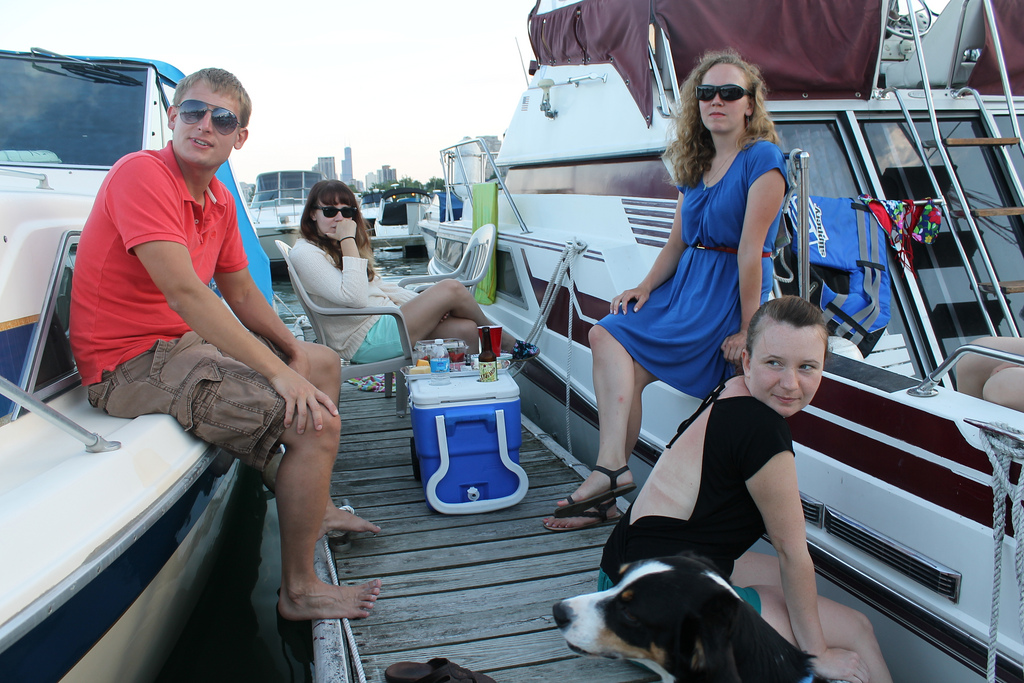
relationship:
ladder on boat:
[903, 6, 1024, 341] [419, 6, 1016, 676]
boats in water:
[242, 141, 472, 273] [283, 300, 297, 318]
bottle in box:
[426, 333, 455, 381] [398, 352, 539, 510]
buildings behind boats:
[300, 143, 407, 187] [251, 164, 459, 247]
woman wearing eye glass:
[543, 43, 794, 528] [692, 84, 757, 104]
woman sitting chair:
[273, 169, 542, 377] [270, 227, 428, 433]